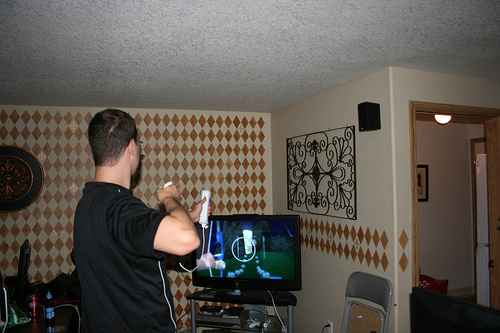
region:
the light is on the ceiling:
[419, 102, 467, 142]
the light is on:
[413, 95, 468, 152]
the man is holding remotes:
[39, 85, 231, 300]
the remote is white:
[141, 154, 223, 255]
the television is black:
[164, 194, 316, 309]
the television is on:
[145, 177, 310, 313]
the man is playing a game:
[53, 84, 268, 326]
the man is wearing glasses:
[80, 103, 152, 164]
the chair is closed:
[307, 250, 398, 329]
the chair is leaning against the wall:
[330, 254, 419, 325]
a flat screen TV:
[185, 213, 303, 305]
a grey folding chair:
[340, 269, 390, 331]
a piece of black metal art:
[284, 124, 358, 222]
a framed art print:
[415, 162, 430, 202]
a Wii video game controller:
[200, 187, 210, 226]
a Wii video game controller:
[165, 180, 170, 187]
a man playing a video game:
[70, 107, 212, 332]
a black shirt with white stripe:
[72, 180, 179, 330]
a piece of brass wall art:
[0, 142, 43, 212]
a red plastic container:
[418, 271, 448, 293]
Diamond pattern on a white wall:
[148, 116, 270, 196]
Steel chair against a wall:
[340, 270, 391, 327]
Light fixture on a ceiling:
[434, 111, 451, 123]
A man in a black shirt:
[72, 108, 208, 331]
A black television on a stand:
[188, 213, 303, 298]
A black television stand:
[183, 285, 298, 332]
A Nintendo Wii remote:
[162, 176, 210, 227]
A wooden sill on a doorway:
[408, 96, 499, 313]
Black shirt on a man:
[71, 181, 180, 326]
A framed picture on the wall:
[416, 162, 429, 203]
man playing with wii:
[71, 109, 219, 328]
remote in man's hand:
[193, 181, 215, 236]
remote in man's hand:
[154, 171, 184, 199]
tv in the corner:
[210, 203, 304, 294]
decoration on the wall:
[280, 128, 363, 221]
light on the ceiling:
[434, 103, 451, 128]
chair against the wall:
[335, 266, 400, 326]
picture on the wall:
[415, 158, 430, 210]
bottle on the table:
[43, 285, 58, 327]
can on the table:
[25, 296, 42, 328]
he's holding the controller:
[198, 192, 212, 229]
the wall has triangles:
[188, 126, 211, 144]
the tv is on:
[223, 229, 260, 262]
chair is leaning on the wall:
[360, 267, 380, 288]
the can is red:
[28, 301, 38, 314]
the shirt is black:
[93, 228, 125, 275]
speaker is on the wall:
[351, 94, 382, 135]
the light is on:
[432, 114, 453, 127]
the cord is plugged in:
[323, 321, 333, 331]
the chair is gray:
[359, 282, 375, 299]